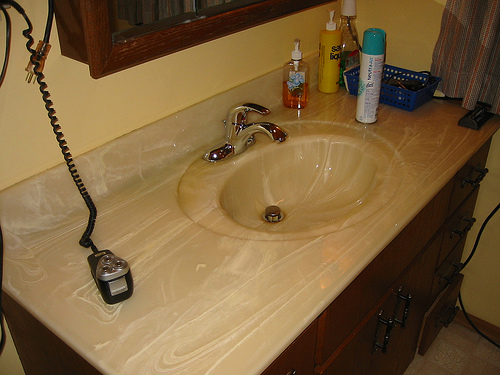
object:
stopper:
[262, 203, 281, 225]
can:
[354, 27, 386, 125]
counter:
[2, 54, 500, 371]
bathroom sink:
[173, 119, 406, 242]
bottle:
[279, 37, 310, 110]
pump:
[290, 37, 303, 60]